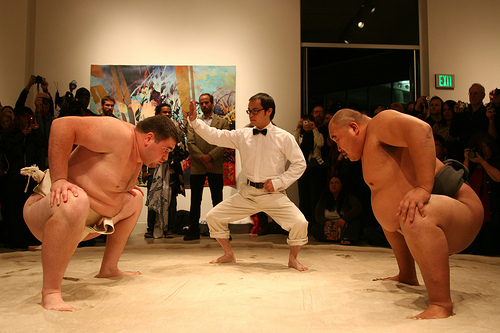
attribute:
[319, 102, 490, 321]
sumo wrestler — bowing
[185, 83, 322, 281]
referee — sumo referree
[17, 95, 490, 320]
wrestlers — ready for match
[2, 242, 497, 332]
ring — sand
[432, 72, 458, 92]
exit sign — green, white, green light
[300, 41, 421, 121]
doorway — open, double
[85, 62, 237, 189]
picture — large, art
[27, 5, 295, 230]
wall — white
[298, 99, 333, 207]
person — photographing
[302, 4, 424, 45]
window — glass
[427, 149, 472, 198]
loincloth — black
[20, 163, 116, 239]
loincloth — white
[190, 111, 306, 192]
shirt — white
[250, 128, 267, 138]
bowtie — black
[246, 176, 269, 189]
belt — black